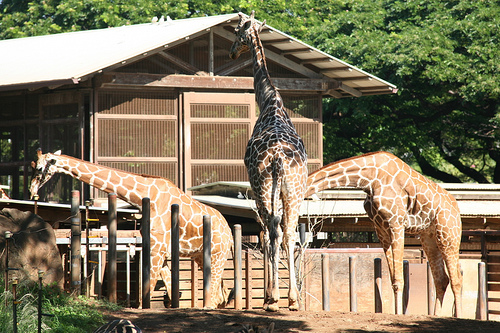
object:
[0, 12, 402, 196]
building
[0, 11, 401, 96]
roof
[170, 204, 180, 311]
pole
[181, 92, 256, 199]
gate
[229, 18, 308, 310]
giraffe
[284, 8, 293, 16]
bird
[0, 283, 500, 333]
ground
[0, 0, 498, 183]
tree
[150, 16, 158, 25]
bird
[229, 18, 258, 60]
head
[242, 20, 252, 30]
ear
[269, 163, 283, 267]
tail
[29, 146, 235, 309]
giraffe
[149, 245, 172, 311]
front legs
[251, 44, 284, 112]
neck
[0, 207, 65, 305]
boulder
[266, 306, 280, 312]
hoof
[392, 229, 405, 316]
leg